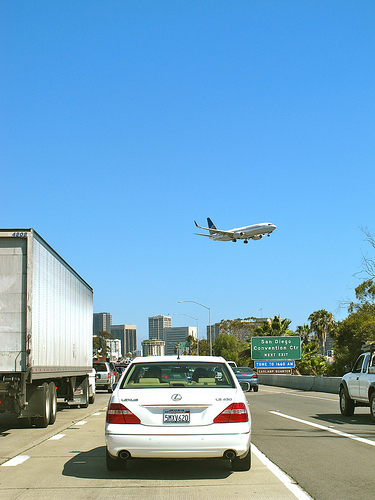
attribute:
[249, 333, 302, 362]
sign — green, white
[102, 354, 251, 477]
car — lexus, white, luxury car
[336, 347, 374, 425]
truck — white, tractor trailer, driving, pickup truck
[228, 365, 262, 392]
car — blue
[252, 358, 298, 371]
street sign — blue, white, brown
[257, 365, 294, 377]
street sign — brown, white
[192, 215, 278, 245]
airplane — flying, white, airborne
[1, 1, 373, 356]
sky — blue, cloudless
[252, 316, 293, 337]
palm tree — tall, green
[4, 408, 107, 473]
line — dotted, white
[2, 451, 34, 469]
hash mark — white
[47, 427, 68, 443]
hash mark — white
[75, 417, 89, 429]
hash mark — white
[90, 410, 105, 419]
hash mark — white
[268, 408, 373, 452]
line — white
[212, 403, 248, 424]
tail light — red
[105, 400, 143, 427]
tail light — red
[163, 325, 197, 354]
building — distant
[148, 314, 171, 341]
building — distant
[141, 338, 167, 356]
building — distant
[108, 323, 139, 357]
building — distant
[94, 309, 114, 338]
building — distant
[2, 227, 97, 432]
truck — semi, 18-wheeler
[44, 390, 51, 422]
rim — white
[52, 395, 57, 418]
rim — white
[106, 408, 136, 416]
light — white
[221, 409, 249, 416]
light — white